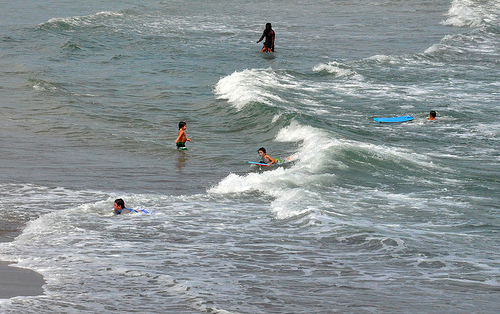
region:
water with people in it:
[5, 23, 486, 298]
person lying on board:
[104, 185, 156, 222]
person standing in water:
[166, 110, 196, 155]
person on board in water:
[247, 145, 302, 181]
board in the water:
[371, 111, 412, 127]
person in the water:
[425, 105, 440, 125]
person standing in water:
[251, 15, 280, 52]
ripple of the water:
[208, 59, 356, 153]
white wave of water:
[226, 173, 325, 203]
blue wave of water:
[79, 56, 206, 98]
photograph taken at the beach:
[53, 14, 480, 245]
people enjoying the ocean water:
[59, 15, 468, 246]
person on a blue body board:
[241, 140, 306, 180]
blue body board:
[362, 108, 417, 130]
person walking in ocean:
[165, 110, 196, 162]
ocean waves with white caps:
[210, 56, 325, 224]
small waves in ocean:
[30, 3, 150, 84]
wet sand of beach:
[0, 243, 45, 303]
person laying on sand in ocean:
[102, 188, 157, 236]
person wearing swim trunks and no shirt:
[161, 113, 202, 158]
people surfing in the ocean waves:
[72, 16, 471, 237]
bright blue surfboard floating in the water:
[360, 105, 419, 132]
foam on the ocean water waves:
[288, 114, 375, 183]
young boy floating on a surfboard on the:
[235, 138, 292, 176]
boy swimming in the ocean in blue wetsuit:
[105, 190, 173, 230]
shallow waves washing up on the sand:
[9, 179, 76, 306]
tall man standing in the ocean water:
[245, 14, 287, 76]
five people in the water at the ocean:
[67, 14, 464, 234]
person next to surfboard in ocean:
[361, 100, 456, 152]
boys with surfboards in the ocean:
[156, 99, 454, 201]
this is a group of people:
[135, 119, 307, 188]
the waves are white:
[278, 103, 319, 188]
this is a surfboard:
[341, 66, 430, 140]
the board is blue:
[370, 94, 408, 144]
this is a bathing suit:
[151, 138, 206, 151]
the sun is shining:
[212, 142, 314, 237]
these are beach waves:
[259, 151, 374, 218]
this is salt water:
[275, 141, 412, 309]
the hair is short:
[84, 196, 135, 220]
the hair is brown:
[106, 191, 173, 236]